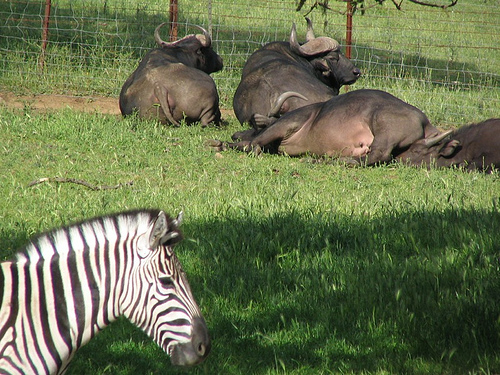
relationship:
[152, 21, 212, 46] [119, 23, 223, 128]
horns to animal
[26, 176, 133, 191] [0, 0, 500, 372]
branch in grass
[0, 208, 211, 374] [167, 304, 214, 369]
animal has nose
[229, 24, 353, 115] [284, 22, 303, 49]
animal has horn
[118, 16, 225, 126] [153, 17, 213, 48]
animal has horns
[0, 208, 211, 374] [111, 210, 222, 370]
animal has head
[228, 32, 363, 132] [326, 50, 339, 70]
animal has eye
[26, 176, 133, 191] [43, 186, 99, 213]
branch laying in grass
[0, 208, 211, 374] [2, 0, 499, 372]
animal ln greengrass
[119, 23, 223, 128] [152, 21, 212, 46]
animal has horns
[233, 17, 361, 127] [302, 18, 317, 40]
animal has horn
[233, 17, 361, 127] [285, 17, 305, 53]
animal has horn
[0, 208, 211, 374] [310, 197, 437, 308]
animal standing in field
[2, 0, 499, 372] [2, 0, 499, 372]
greengrass in greengrass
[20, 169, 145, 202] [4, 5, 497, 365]
branch in ground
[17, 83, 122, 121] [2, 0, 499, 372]
brown dirt in greengrass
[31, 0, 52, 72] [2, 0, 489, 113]
post in fence